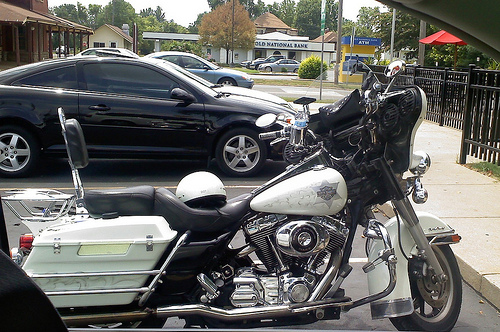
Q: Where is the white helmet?
A: On the motorcycle seat.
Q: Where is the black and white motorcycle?
A: Parked in a lot.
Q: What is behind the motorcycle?
A: Black car.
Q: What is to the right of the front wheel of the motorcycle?
A: Sidewalk.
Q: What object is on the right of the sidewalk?
A: Black metal fence.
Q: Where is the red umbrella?
A: In the background on the right.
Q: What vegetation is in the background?
A: Green trees.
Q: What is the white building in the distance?
A: A bank.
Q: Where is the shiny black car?
A: Behind the motorcycle.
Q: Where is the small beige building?
A: In the background on the left.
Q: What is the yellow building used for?
A: Holding an ATM.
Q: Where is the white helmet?
A: On the motorcycle seat.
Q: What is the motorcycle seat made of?
A: Black leather.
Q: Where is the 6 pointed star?
A: On the body of the motorcycle.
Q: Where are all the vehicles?
A: In a parking lot.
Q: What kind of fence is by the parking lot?
A: Black iron.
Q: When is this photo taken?
A: During the daytime.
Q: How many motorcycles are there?
A: Just one.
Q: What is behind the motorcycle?
A: Cars.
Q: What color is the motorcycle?
A: White and silver.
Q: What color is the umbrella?
A: Red.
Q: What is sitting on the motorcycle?
A: A helmet.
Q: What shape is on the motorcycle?
A: A star.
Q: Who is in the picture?
A: No people.